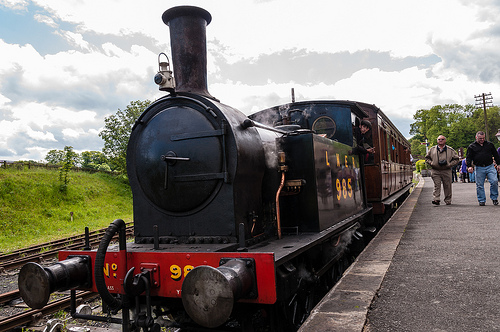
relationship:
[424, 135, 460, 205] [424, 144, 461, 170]
man has jacket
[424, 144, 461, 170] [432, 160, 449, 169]
jacket has pockets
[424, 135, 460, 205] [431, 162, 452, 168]
man has hands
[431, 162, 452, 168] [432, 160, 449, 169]
hands in pockets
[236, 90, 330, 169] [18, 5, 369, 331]
smoke coming out of engine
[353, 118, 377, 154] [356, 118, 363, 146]
man hanging out of window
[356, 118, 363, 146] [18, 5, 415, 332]
window on train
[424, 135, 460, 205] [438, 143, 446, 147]
man has neck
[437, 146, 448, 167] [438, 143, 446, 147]
camera hanging from neck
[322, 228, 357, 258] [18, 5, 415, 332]
smoke coming from under train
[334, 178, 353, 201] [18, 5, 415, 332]
number 985 on train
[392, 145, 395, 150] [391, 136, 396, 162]
light coming from window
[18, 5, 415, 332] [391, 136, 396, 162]
train has window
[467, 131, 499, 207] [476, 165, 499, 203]
man has jeans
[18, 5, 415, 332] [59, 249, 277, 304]
train has fender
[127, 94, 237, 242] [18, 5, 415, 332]
front of train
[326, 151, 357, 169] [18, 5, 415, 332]
letters on train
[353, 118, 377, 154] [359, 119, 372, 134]
man poking out h head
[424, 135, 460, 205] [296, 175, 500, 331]
man walking on sidewalk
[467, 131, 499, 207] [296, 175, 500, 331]
man walking on sidewalk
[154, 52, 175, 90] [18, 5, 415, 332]
lantern on train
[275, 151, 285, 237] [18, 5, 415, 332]
steam pipe on train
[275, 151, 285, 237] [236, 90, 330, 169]
steam pipe shooting out smoke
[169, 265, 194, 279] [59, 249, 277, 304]
number on fender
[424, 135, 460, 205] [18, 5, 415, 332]
man near train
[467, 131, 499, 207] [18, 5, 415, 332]
man near train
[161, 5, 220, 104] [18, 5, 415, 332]
smoke stack on train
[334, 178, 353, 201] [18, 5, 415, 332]
number 985 painted on train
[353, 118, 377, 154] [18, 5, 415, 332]
man inside train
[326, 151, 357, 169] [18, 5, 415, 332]
letters painted on train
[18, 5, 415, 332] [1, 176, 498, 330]
train in railway station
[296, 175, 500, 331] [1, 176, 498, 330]
sidewalk of railway station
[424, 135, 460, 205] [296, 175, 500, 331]
man on sidewalk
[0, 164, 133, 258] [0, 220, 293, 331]
grass near track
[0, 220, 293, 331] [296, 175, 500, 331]
track near sidewalk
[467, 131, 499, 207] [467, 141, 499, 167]
man wearing shirt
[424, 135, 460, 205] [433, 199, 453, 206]
man has shoes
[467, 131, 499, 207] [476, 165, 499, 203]
man wearing jeans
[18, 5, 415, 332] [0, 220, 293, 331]
train on track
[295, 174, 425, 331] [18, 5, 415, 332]
curb next to train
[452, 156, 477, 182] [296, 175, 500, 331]
group of people on sidewalk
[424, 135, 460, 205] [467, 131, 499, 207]
man next to man